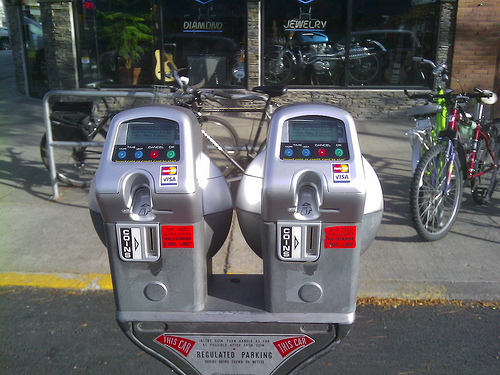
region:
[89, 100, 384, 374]
two metal parking meters by curb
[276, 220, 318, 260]
coin slot on parking meter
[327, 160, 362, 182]
credit card logo on pasrking meter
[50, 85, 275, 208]
bike rack behind parking meter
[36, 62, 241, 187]
black bicycle parked next to bike rack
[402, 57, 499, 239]
green bicycle parked next to red bicycle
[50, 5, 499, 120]
store behind parking meter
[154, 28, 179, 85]
guitar in store window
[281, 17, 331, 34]
neon sign in window is off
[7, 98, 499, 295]
cement sidewalk behind parking meter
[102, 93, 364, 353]
parking meters in front of store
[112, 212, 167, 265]
coin slot on a parking meter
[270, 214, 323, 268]
coin slot on a parking meter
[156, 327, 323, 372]
sign on a parking meter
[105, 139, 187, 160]
four buttons on a parking meter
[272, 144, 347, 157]
four buttons on a parking meter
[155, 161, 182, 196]
credit card sticker on a parking meter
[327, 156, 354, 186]
credit card sticker on a parking meter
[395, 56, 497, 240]
bicycles parked near a parking meter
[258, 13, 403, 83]
motorcycle in a storefront window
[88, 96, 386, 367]
twin coin parking meters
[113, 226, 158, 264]
a coin insertion slot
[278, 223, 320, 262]
a coin insertion slot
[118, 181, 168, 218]
credit card insertion slot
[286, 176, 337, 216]
credit card insertion slot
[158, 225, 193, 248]
a bright red sticker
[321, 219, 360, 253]
a bright red sticker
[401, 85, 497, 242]
a parked bicycle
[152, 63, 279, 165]
a parked silver bicycle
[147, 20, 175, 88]
a beige guitar in window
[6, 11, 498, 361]
A street scene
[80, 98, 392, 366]
These are parking meters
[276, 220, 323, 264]
The parking meter's coin slot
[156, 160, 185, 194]
This meter takes credit cards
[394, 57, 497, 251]
Bicycles are on the sidewalk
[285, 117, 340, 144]
A digital display screen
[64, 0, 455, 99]
These are storefront windows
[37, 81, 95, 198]
This is a bike rack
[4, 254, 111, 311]
A street curb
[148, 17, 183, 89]
A guitar is in the window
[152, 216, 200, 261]
small red sign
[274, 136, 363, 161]
colored buttons on the machine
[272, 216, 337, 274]
coin slot on the machine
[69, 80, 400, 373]
a machine on the street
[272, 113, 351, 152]
small computer screen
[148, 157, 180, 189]
a small white sticker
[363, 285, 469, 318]
leaves and debris on the curb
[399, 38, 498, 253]
bicycles parked on the curb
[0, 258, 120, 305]
yellow painted curb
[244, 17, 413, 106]
a bike in the window